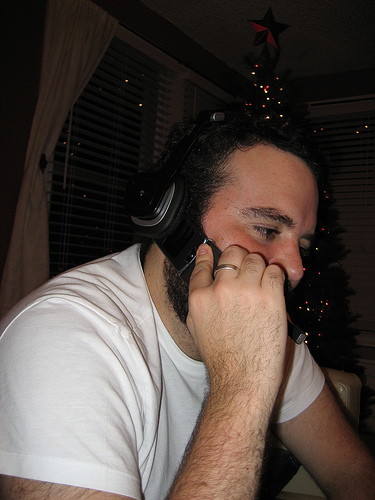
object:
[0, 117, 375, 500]
man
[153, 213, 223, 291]
cellphone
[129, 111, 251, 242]
headphones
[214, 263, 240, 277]
ring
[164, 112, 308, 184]
black hair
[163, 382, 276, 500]
hairy arm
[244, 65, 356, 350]
christmas tree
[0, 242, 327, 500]
white shirt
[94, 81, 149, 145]
blinds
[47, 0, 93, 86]
curtains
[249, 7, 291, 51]
star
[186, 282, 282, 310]
knuckle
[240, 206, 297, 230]
eyebrow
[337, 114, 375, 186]
mini blinds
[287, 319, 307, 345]
microphone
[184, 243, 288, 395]
hand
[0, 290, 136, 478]
shoulder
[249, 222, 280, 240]
eye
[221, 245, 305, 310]
part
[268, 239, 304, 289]
nose